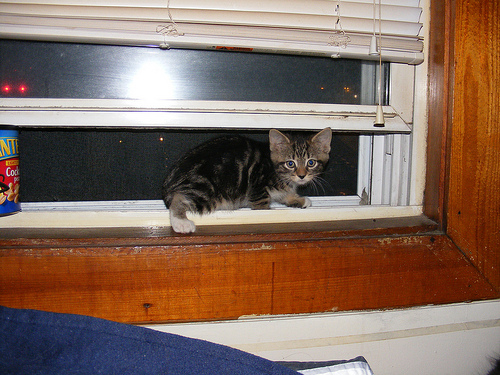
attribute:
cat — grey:
[160, 126, 332, 235]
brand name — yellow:
[0, 137, 22, 159]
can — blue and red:
[0, 122, 25, 218]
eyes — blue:
[259, 136, 341, 164]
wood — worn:
[1, 1, 498, 323]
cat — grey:
[142, 129, 343, 228]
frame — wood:
[8, 12, 499, 337]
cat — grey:
[172, 111, 379, 251]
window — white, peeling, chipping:
[1, 2, 429, 227]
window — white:
[1, 0, 435, 205]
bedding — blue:
[3, 297, 378, 373]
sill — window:
[2, 201, 455, 246]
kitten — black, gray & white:
[187, 136, 324, 211]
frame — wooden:
[1, 214, 499, 325]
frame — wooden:
[421, 1, 499, 300]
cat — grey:
[148, 125, 335, 238]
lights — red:
[0, 83, 30, 94]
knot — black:
[135, 295, 157, 310]